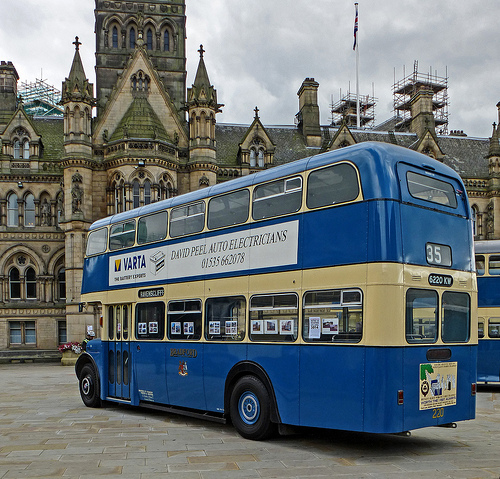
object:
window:
[7, 280, 22, 301]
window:
[21, 206, 37, 228]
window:
[403, 287, 443, 347]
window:
[404, 168, 459, 210]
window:
[203, 186, 251, 231]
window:
[303, 161, 360, 212]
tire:
[226, 372, 273, 441]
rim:
[238, 393, 258, 422]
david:
[170, 245, 192, 260]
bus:
[74, 141, 483, 443]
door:
[120, 302, 135, 400]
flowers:
[85, 322, 96, 339]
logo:
[114, 257, 122, 274]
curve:
[393, 160, 469, 218]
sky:
[1, 0, 500, 142]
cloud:
[0, 0, 499, 142]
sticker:
[168, 320, 182, 336]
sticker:
[181, 320, 195, 338]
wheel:
[77, 362, 101, 409]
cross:
[252, 104, 261, 117]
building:
[0, 0, 499, 365]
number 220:
[430, 405, 446, 419]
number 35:
[425, 242, 441, 267]